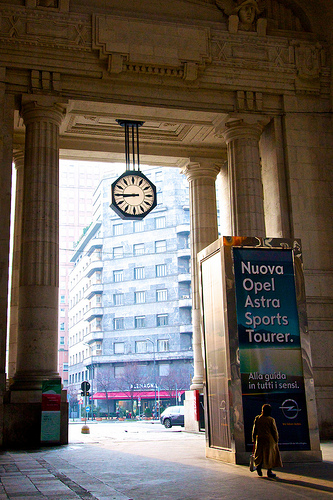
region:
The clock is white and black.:
[110, 174, 173, 217]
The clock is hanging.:
[95, 114, 168, 231]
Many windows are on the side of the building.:
[72, 178, 213, 411]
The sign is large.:
[202, 227, 323, 461]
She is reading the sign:
[240, 403, 288, 484]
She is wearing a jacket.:
[233, 391, 289, 485]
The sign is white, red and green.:
[27, 366, 82, 474]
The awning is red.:
[76, 379, 200, 407]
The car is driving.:
[152, 395, 187, 438]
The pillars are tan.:
[19, 104, 78, 418]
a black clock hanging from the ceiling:
[106, 115, 161, 221]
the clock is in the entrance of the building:
[107, 115, 163, 231]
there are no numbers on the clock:
[109, 167, 158, 223]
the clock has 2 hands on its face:
[113, 191, 144, 199]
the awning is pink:
[92, 392, 188, 401]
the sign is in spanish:
[238, 257, 298, 349]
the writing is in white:
[241, 262, 294, 346]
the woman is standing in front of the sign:
[240, 397, 297, 483]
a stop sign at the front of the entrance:
[75, 379, 99, 437]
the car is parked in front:
[159, 403, 186, 430]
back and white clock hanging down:
[106, 116, 165, 227]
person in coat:
[247, 401, 295, 479]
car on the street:
[152, 400, 193, 440]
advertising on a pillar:
[200, 237, 319, 405]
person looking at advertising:
[199, 243, 332, 479]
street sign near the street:
[72, 374, 108, 445]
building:
[65, 229, 194, 432]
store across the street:
[92, 375, 197, 434]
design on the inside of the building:
[1, 2, 331, 110]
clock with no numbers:
[105, 167, 163, 223]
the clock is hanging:
[84, 108, 163, 277]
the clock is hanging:
[99, 97, 179, 220]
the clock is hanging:
[109, 102, 198, 292]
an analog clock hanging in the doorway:
[107, 115, 162, 225]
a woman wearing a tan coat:
[250, 400, 287, 474]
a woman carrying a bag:
[246, 400, 290, 481]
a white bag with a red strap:
[247, 443, 255, 469]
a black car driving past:
[155, 401, 193, 430]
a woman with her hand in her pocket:
[240, 401, 283, 480]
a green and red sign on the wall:
[37, 372, 66, 447]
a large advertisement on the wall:
[227, 244, 305, 411]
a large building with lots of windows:
[76, 266, 182, 390]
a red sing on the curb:
[185, 390, 205, 430]